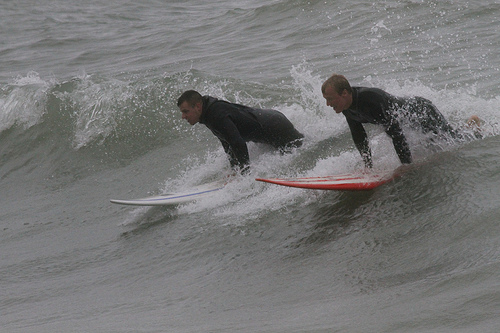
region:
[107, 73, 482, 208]
two men surfing together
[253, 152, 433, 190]
a red with white stripe surf board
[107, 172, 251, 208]
a white surf board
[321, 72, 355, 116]
a man with blonde hair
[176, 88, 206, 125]
a man with dark hair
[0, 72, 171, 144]
the waves of the ocean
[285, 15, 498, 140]
water crashing into surfers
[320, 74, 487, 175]
a man in a black wet suit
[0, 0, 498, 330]
the ocean with waves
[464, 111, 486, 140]
a man's foot in the water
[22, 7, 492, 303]
Some men are out in the ocean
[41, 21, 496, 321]
Some men are on their surfboards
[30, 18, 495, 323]
Some men are getting very wet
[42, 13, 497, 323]
Some men are on their vacation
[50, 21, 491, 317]
Some men are wearing their wetsuits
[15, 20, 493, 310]
Some men are being very careful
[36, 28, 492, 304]
Some men are getting some exercise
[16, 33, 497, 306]
Some men are doing some surfing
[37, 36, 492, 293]
Some men are out in the daytime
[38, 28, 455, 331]
The men are enjoying the day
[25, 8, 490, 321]
Some people are out in the ocean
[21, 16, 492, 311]
Some people are on their surfboards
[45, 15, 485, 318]
Some people are wearing their wetsuits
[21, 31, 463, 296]
Some people are on an ocean wave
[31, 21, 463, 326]
Some people are getting some exercise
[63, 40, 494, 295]
Some people are on their day off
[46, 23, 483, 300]
Some people are close to the beach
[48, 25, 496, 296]
Some people are testing their skills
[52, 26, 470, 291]
Some people are out in the daytime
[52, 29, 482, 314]
Some people are enjoying their day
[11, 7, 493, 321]
an instructor is teaching a student to surf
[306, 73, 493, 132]
the teacher is giving instructions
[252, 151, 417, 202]
the surfboard is red and white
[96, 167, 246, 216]
the surfboard is white with a stripe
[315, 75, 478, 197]
man is wearing a full wetsuit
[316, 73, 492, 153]
the man's feet are bare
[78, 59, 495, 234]
the men are catching a wave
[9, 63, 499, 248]
the small wave is about to break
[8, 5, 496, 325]
the ocean is choppy with swells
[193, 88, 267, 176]
the man is wearing a black hoodie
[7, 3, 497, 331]
The ocean.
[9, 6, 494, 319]
Two men on surfboards.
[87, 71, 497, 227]
The men are surfing.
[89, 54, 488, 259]
The surfers are in the water.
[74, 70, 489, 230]
The two men are kneeling on the surfboards.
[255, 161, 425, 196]
The surfboard on the right is white and red.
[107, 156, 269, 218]
The surfboard on the left is white.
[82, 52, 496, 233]
The surfers are wearing black wetsuits.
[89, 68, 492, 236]
Two men ride the same wave.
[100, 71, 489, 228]
The two men are surfing together.